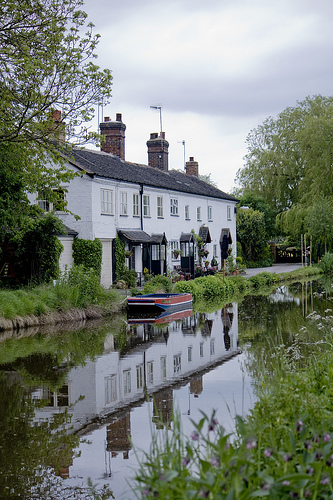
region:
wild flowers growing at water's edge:
[145, 407, 326, 492]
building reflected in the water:
[77, 336, 247, 422]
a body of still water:
[4, 285, 327, 422]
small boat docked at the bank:
[120, 284, 193, 315]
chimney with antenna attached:
[172, 125, 202, 174]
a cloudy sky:
[170, 58, 275, 110]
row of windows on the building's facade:
[94, 184, 231, 221]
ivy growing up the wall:
[70, 228, 127, 271]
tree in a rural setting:
[237, 87, 327, 276]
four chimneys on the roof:
[41, 99, 217, 176]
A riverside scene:
[13, 91, 316, 375]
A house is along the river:
[15, 106, 266, 316]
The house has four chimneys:
[44, 108, 212, 176]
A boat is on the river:
[123, 288, 205, 320]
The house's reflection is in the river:
[20, 314, 255, 460]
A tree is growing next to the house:
[2, 88, 107, 244]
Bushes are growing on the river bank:
[182, 271, 251, 306]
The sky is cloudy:
[177, 43, 261, 128]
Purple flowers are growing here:
[183, 416, 328, 489]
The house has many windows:
[97, 186, 235, 224]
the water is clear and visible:
[100, 388, 207, 499]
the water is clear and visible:
[108, 255, 238, 495]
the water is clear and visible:
[135, 357, 206, 483]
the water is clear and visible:
[113, 327, 181, 486]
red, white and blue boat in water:
[119, 285, 198, 314]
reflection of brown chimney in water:
[104, 408, 140, 462]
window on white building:
[96, 183, 116, 219]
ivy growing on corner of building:
[75, 235, 105, 273]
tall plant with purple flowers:
[197, 431, 323, 491]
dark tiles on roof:
[88, 152, 139, 182]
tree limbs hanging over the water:
[5, 94, 70, 203]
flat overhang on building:
[121, 228, 159, 246]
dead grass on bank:
[9, 308, 87, 325]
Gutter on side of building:
[136, 182, 145, 227]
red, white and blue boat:
[125, 287, 202, 321]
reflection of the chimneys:
[99, 406, 186, 462]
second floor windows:
[83, 176, 230, 227]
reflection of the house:
[22, 328, 272, 407]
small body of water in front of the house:
[20, 303, 293, 388]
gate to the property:
[269, 235, 308, 268]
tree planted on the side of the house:
[7, 134, 67, 236]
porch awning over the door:
[117, 226, 160, 256]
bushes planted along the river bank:
[176, 276, 259, 297]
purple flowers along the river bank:
[179, 409, 305, 486]